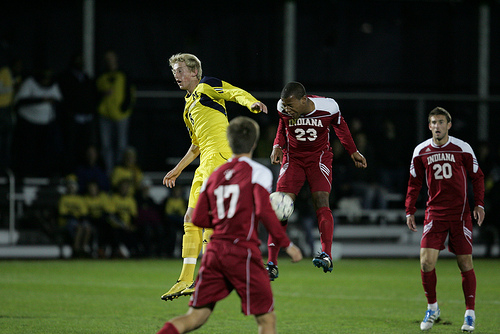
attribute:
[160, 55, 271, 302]
person — kicking, jumping, blond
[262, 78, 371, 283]
man — jumping, black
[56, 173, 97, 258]
person — sitting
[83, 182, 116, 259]
person — sitting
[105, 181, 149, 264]
child — sitting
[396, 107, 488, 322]
man — exhausted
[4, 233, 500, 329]
field — green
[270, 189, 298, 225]
soccer ball — black, white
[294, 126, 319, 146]
number — twenty three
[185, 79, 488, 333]
men — playing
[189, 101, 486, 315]
uniforms — red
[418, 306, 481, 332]
shoes — white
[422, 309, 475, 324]
laces — blue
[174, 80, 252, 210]
uniform — yellow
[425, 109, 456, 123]
hair — brown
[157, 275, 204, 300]
shoes — yellow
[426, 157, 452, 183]
number — twenty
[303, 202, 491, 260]
benches — empty, silver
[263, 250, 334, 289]
shoes — white, black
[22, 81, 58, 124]
shirt — white